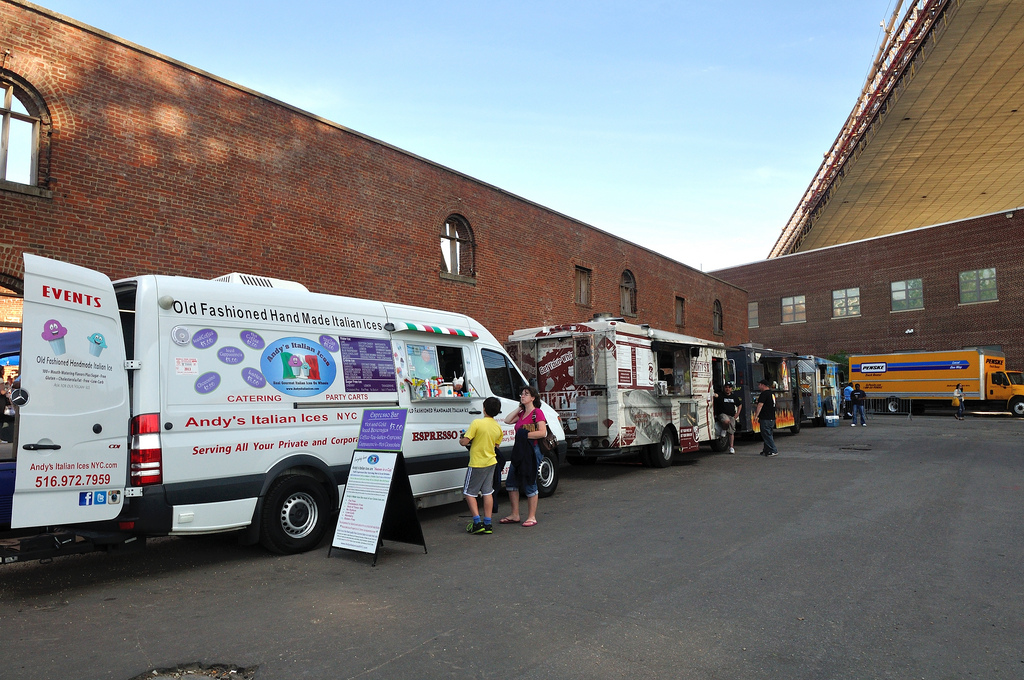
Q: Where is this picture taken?
A: At a event.